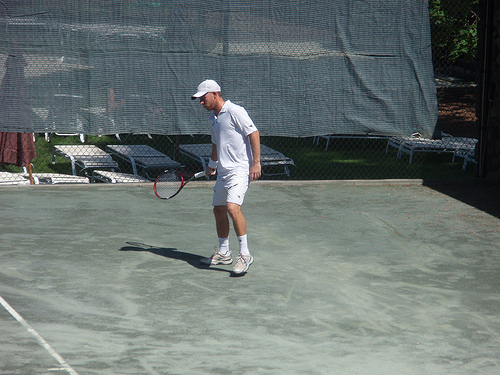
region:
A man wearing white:
[185, 83, 291, 294]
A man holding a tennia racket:
[146, 75, 299, 290]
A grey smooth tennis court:
[318, 296, 446, 373]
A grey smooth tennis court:
[287, 182, 492, 292]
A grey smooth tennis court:
[144, 309, 269, 373]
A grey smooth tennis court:
[18, 184, 90, 313]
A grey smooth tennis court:
[8, 336, 60, 373]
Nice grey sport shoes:
[194, 234, 254, 293]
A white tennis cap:
[186, 71, 218, 104]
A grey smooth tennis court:
[6, 236, 198, 291]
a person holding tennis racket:
[153, 66, 273, 275]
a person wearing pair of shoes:
[204, 235, 254, 278]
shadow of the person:
[125, 231, 207, 269]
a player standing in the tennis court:
[138, 69, 292, 307]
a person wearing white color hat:
[188, 73, 224, 98]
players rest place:
[50, 136, 188, 176]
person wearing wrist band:
[208, 153, 216, 171]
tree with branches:
[436, 10, 478, 60]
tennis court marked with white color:
[1, 299, 66, 374]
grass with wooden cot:
[36, 142, 111, 175]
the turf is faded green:
[152, 295, 267, 368]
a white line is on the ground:
[10, 305, 42, 366]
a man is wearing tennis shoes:
[187, 230, 308, 313]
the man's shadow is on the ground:
[122, 222, 362, 322]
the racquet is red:
[142, 153, 286, 260]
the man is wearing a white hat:
[187, 73, 234, 116]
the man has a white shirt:
[163, 94, 370, 216]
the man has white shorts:
[196, 156, 343, 221]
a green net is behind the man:
[111, 48, 493, 164]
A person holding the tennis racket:
[128, 73, 269, 289]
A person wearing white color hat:
[187, 69, 223, 108]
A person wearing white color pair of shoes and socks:
[198, 234, 264, 277]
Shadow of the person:
[115, 234, 203, 281]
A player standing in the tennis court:
[105, 65, 290, 294]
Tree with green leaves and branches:
[439, 14, 467, 65]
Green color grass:
[308, 149, 361, 174]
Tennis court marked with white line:
[1, 299, 63, 364]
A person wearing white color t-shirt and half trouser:
[210, 98, 257, 213]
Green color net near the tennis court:
[318, 11, 447, 166]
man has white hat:
[180, 82, 244, 114]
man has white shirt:
[201, 105, 252, 189]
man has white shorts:
[219, 163, 250, 225]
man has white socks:
[202, 234, 264, 280]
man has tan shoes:
[202, 234, 272, 301]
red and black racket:
[138, 162, 209, 212]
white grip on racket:
[172, 155, 233, 205]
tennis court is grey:
[61, 199, 158, 302]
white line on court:
[0, 286, 75, 357]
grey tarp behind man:
[4, 7, 384, 105]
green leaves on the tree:
[441, 56, 466, 73]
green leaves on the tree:
[469, 22, 495, 68]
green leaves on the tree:
[455, 19, 477, 58]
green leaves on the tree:
[431, 5, 463, 47]